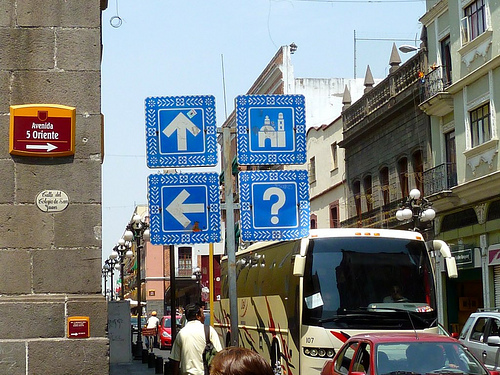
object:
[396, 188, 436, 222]
lamp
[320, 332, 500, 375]
car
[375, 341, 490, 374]
windshield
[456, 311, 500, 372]
car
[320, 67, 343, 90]
ground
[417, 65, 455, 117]
balcony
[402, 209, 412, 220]
light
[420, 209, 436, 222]
light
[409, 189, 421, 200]
light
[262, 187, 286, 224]
question mark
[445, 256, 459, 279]
view mirror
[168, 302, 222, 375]
man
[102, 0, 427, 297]
sky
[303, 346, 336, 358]
headlight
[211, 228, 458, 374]
bus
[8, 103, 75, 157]
sign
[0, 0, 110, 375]
wall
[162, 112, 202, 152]
arrow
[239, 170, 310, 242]
blue sign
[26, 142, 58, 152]
arrow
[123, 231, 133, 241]
light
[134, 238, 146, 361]
lamp post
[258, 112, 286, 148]
church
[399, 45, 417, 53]
security camera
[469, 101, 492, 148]
window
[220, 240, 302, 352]
windows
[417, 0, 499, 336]
building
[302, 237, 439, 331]
window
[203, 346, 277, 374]
hair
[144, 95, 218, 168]
blue sign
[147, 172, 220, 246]
blue sign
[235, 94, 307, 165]
blue sign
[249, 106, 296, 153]
building pic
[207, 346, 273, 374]
person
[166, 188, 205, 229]
arrow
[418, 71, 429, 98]
person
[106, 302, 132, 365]
street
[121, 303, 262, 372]
street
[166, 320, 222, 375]
shirt